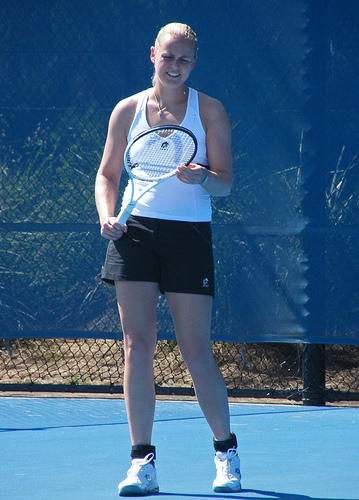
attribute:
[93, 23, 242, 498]
woman — young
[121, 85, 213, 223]
tank top — white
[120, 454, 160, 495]
tennis shoe — white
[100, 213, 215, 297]
shorts — black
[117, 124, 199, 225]
tennis racket — white, black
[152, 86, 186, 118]
necklace — gold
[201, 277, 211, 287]
logo — white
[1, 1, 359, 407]
fence — chain link, metal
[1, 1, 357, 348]
netting — blue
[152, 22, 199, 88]
hair — blonde, blond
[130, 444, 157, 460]
ankle weight — black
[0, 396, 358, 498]
tennis court — blue